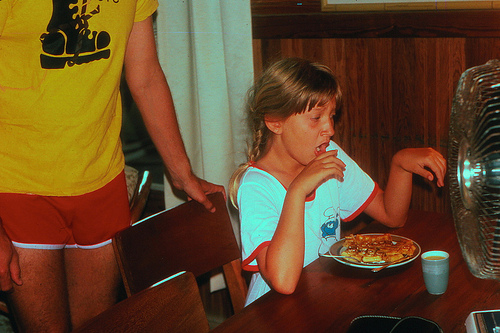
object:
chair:
[64, 271, 214, 333]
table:
[212, 210, 500, 333]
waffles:
[360, 248, 383, 262]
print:
[320, 207, 341, 235]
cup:
[418, 250, 448, 293]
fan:
[444, 58, 499, 278]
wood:
[250, 10, 499, 221]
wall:
[251, 2, 500, 219]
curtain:
[153, 0, 262, 296]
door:
[115, 81, 164, 191]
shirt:
[0, 0, 163, 198]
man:
[1, 0, 229, 333]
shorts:
[0, 166, 132, 250]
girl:
[228, 56, 448, 309]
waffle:
[381, 248, 403, 264]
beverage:
[423, 255, 446, 260]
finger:
[314, 145, 327, 154]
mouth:
[314, 141, 332, 156]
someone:
[1, 0, 229, 333]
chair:
[110, 192, 249, 322]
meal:
[338, 233, 419, 265]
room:
[1, 1, 500, 333]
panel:
[250, 11, 500, 237]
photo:
[1, 1, 500, 333]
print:
[37, 0, 111, 70]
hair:
[225, 57, 343, 208]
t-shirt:
[236, 140, 381, 309]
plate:
[326, 233, 422, 270]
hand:
[390, 146, 446, 188]